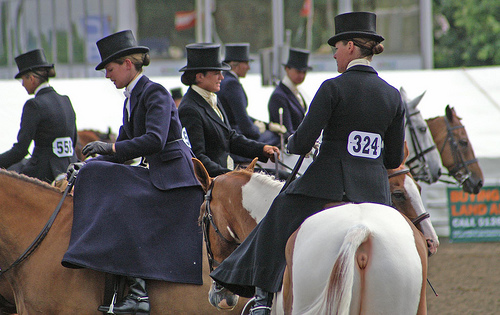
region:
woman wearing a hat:
[268, 10, 409, 213]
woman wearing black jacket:
[265, 8, 425, 228]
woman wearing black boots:
[235, 5, 416, 310]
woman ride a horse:
[235, 5, 425, 310]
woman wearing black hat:
[77, 22, 192, 282]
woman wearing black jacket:
[60, 32, 210, 307]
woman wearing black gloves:
[80, 33, 196, 298]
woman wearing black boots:
[67, 30, 197, 307]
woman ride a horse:
[72, 26, 191, 301]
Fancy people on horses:
[0, 10, 485, 314]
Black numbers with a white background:
[343, 125, 383, 162]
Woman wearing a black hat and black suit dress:
[65, 25, 207, 313]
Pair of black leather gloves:
[63, 137, 113, 186]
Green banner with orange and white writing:
[446, 183, 498, 245]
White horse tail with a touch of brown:
[290, 223, 372, 314]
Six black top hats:
[14, 10, 384, 82]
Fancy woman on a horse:
[190, 10, 435, 314]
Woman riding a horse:
[1, 27, 253, 314]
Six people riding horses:
[1, 9, 486, 314]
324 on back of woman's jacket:
[346, 130, 383, 160]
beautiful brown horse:
[1, 170, 253, 313]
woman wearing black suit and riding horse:
[210, 10, 407, 313]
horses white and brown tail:
[301, 224, 370, 313]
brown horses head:
[420, 105, 485, 194]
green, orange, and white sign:
[446, 185, 498, 240]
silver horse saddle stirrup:
[106, 274, 121, 313]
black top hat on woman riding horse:
[179, 41, 232, 73]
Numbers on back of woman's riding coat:
[51, 135, 76, 157]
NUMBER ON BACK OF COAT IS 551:
[44, 129, 92, 164]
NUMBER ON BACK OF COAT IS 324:
[343, 129, 394, 161]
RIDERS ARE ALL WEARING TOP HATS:
[8, 9, 388, 78]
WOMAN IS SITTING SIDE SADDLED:
[65, 27, 215, 304]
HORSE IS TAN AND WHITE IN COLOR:
[191, 153, 439, 311]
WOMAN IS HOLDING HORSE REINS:
[250, 127, 324, 223]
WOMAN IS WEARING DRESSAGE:
[232, 64, 420, 288]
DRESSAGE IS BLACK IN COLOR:
[76, 74, 223, 274]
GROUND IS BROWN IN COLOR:
[433, 241, 498, 306]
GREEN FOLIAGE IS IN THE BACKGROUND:
[438, 5, 499, 65]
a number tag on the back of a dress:
[346, 129, 381, 157]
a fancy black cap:
[328, 12, 383, 43]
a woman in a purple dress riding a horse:
[0, 30, 199, 312]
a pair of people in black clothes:
[175, 39, 280, 180]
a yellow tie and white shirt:
[205, 93, 225, 119]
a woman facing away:
[279, 13, 413, 204]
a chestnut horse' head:
[430, 107, 485, 197]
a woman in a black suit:
[0, 40, 82, 181]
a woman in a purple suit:
[63, 18, 205, 286]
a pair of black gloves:
[79, 133, 114, 158]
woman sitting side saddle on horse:
[74, 25, 199, 285]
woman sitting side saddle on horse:
[284, 18, 404, 213]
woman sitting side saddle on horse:
[9, 48, 79, 172]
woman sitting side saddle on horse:
[172, 31, 229, 164]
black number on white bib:
[340, 121, 383, 163]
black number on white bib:
[37, 128, 77, 168]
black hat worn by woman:
[327, 3, 385, 37]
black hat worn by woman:
[181, 37, 223, 75]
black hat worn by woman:
[11, 37, 58, 73]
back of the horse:
[270, 189, 430, 312]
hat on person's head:
[78, 24, 155, 69]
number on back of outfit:
[330, 111, 397, 172]